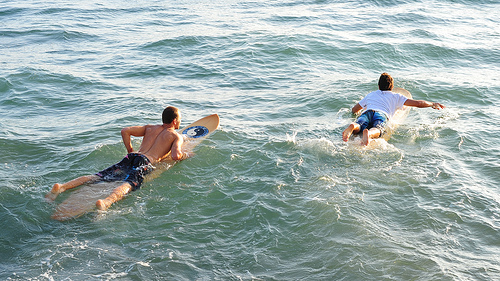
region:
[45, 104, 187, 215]
White guy on surfboard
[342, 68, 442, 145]
White boy on surfboard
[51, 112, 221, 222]
Large long tan surfboard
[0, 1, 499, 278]
Large open green water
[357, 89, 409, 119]
Small shirt sleeved white shirt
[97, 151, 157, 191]
Long black cloth shorts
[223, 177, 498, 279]
sunlight reflecting on somewhat calm green tinted ocean waves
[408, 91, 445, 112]
outstretched human male arm with slightly sunburned skin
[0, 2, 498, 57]
rough, choppy ocean water in the distance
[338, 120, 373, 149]
barefoot feet of man resting on surfboard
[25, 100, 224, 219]
shirtless human male surfing in ocean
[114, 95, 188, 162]
torso of bare-chested man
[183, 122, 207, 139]
decorative ying-yang sign on surfboard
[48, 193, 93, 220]
tip of brown surfboard seen under ocean water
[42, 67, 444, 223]
two men surfing together in the ocean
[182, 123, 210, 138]
Yin yang symbol on board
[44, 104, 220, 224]
Man without shirt riding surfboard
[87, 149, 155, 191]
Black and blue men's shorts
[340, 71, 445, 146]
Man in white shirt laying on board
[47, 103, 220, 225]
Man pushing himself up on board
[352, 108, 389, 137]
Men's plaid board shorts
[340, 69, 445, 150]
Man paddling on board in the water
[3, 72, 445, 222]
Two men riding on surfboards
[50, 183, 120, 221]
Edge of surfboard under the water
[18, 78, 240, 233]
Man is on a surfboard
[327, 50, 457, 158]
Person is on a surfboard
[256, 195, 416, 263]
Waves in the water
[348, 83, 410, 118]
The person has a shirt on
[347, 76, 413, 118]
The person has a white shirt on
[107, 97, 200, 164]
The man doesn't have a shirt on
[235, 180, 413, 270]
Large body of water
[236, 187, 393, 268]
Large body of blue water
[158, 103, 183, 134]
The man has short hair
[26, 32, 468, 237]
Two men in the water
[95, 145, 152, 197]
man wearing blue shorts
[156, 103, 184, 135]
man wearing blond hair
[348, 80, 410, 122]
man wearing a white tee shirt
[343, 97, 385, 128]
man wearing plaid shorts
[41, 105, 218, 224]
man is riding on yellow surfboard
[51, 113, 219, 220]
black, white, and blue logo on surfboard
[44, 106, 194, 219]
man is wearing black swim trunks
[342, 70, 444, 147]
man is wearing a white t-shirt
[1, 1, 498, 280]
water is greenish blue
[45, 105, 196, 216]
man has muscular back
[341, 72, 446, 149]
man is wearing blue swim trunks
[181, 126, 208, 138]
yin yang symbol on logo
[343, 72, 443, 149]
man riding on surfboard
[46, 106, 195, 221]
man has bare feet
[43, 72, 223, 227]
shirtless man on a surfboard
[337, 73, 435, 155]
man wearing white shirt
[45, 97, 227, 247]
surfboard with blue and white logo